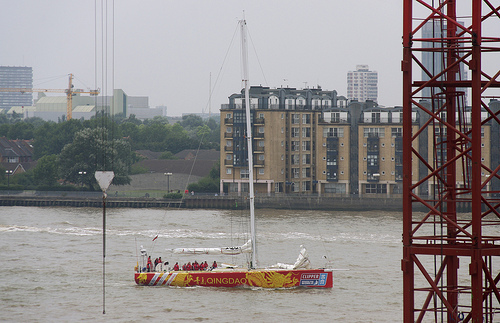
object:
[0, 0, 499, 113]
sky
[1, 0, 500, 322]
scene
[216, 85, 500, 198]
building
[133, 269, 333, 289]
boat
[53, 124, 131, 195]
tree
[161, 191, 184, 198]
leaves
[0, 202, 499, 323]
water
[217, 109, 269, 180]
wall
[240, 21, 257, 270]
pole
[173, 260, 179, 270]
people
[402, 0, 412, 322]
post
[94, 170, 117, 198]
sign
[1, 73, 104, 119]
crane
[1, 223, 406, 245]
wake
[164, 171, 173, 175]
light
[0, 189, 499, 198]
street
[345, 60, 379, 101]
building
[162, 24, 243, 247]
string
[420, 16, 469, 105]
building